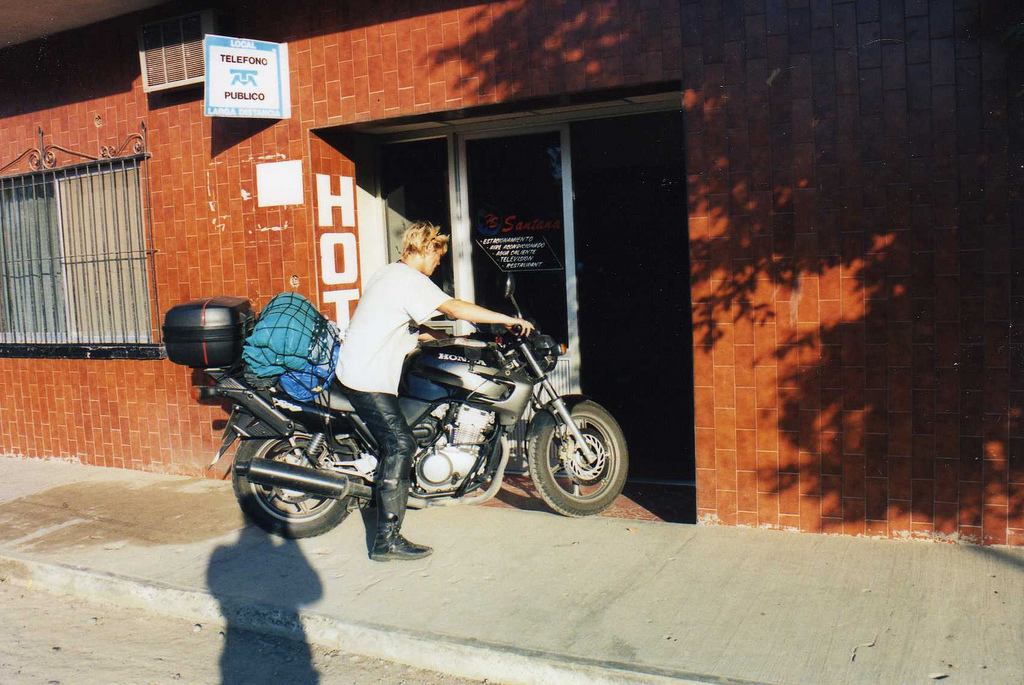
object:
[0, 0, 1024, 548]
building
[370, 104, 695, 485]
door way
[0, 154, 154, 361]
window